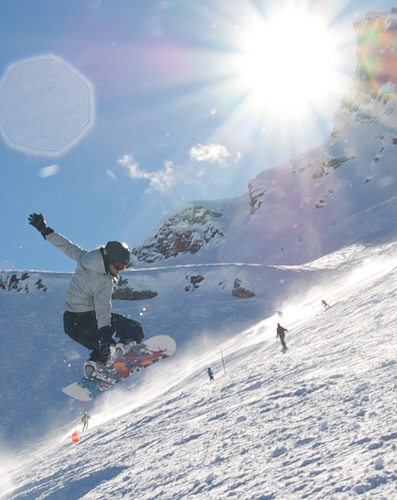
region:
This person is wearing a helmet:
[110, 234, 130, 302]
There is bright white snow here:
[227, 415, 244, 471]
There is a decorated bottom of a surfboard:
[84, 375, 106, 419]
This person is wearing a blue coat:
[205, 370, 232, 416]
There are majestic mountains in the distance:
[178, 195, 209, 267]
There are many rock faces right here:
[134, 278, 149, 332]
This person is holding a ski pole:
[288, 335, 296, 353]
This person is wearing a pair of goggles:
[113, 258, 130, 293]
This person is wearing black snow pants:
[112, 321, 142, 374]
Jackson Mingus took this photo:
[70, 280, 252, 459]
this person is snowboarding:
[17, 203, 179, 408]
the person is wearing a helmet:
[102, 220, 138, 284]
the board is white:
[60, 334, 193, 410]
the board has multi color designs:
[55, 361, 182, 394]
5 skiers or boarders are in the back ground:
[68, 295, 336, 429]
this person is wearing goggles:
[91, 237, 142, 273]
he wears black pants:
[62, 300, 149, 360]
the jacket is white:
[41, 224, 120, 334]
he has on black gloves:
[17, 208, 66, 245]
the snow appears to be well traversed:
[163, 334, 356, 471]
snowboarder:
[24, 203, 158, 392]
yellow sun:
[201, 13, 352, 125]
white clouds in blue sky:
[18, 41, 47, 80]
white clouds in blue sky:
[62, 30, 101, 62]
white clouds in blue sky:
[141, 55, 180, 123]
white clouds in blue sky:
[137, 141, 165, 158]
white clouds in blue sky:
[29, 39, 76, 74]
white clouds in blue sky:
[41, 126, 82, 161]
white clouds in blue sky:
[45, 125, 111, 197]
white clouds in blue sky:
[12, 144, 83, 188]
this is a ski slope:
[9, 69, 364, 476]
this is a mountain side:
[18, 163, 356, 453]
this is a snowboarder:
[26, 210, 168, 347]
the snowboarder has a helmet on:
[71, 230, 159, 246]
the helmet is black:
[99, 239, 141, 266]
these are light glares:
[18, 119, 114, 164]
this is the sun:
[203, 113, 369, 171]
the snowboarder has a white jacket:
[33, 199, 180, 372]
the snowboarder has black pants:
[60, 302, 160, 349]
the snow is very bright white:
[191, 350, 328, 498]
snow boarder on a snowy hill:
[27, 208, 181, 402]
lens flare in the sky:
[1, 30, 115, 168]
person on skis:
[255, 309, 300, 372]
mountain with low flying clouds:
[128, 144, 294, 273]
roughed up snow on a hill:
[231, 361, 362, 473]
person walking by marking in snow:
[199, 342, 240, 387]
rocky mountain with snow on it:
[160, 203, 215, 250]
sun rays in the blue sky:
[198, 104, 372, 200]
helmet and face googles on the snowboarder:
[99, 238, 130, 275]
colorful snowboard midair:
[83, 330, 183, 399]